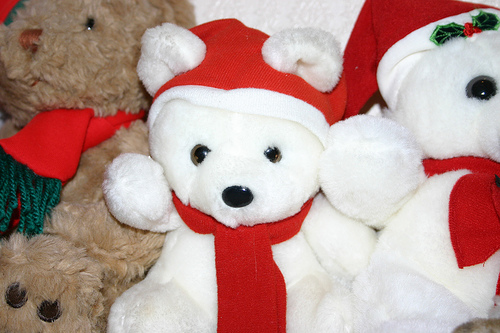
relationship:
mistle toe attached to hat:
[425, 15, 499, 35] [349, 4, 486, 55]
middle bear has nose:
[115, 33, 372, 331] [223, 181, 253, 212]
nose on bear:
[16, 22, 42, 48] [7, 17, 153, 293]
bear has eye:
[340, 49, 500, 319] [454, 75, 500, 106]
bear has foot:
[7, 17, 153, 293] [8, 249, 111, 321]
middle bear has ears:
[115, 33, 372, 331] [140, 29, 337, 85]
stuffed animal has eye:
[340, 49, 500, 319] [454, 75, 500, 106]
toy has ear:
[120, 52, 328, 333] [126, 21, 197, 83]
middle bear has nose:
[115, 33, 372, 331] [16, 22, 42, 48]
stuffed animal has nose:
[340, 49, 500, 319] [481, 118, 500, 146]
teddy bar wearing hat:
[135, 13, 339, 315] [167, 21, 324, 105]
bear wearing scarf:
[7, 17, 153, 293] [4, 105, 103, 215]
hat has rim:
[167, 21, 324, 105] [156, 94, 315, 121]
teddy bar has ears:
[135, 13, 339, 315] [140, 29, 337, 85]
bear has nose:
[7, 17, 153, 293] [16, 22, 42, 48]